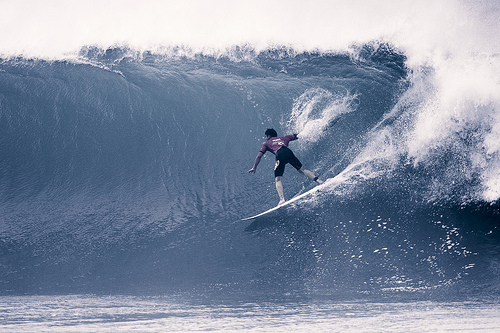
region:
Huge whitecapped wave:
[5, 5, 495, 326]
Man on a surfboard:
[241, 123, 330, 222]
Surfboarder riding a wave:
[2, 35, 497, 327]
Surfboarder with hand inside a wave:
[233, 125, 324, 220]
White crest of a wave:
[1, 18, 499, 82]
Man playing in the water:
[246, 125, 327, 205]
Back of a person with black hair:
[248, 126, 325, 205]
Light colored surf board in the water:
[238, 181, 333, 221]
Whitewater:
[414, 43, 497, 204]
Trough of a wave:
[0, 260, 498, 332]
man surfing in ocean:
[228, 75, 430, 231]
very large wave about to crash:
[16, 23, 430, 297]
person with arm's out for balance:
[229, 110, 377, 231]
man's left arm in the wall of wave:
[277, 112, 328, 151]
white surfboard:
[240, 169, 370, 230]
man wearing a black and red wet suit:
[230, 111, 367, 223]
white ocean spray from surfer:
[399, 29, 478, 157]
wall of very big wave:
[52, 32, 188, 307]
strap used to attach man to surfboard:
[308, 166, 330, 195]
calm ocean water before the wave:
[67, 295, 342, 326]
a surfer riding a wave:
[223, 102, 390, 215]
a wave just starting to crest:
[10, 18, 417, 136]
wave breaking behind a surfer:
[278, 49, 499, 196]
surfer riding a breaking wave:
[214, 93, 385, 222]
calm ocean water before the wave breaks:
[34, 297, 415, 332]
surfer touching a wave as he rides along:
[281, 117, 326, 142]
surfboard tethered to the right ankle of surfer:
[305, 171, 349, 193]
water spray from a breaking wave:
[397, 43, 493, 112]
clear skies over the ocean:
[15, 7, 242, 32]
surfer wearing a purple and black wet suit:
[240, 127, 314, 192]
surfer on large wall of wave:
[5, 40, 495, 316]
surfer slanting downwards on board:
[236, 105, 356, 252]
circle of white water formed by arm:
[282, 70, 357, 147]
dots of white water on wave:
[275, 215, 476, 300]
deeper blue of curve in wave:
[5, 75, 200, 250]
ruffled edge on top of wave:
[5, 26, 395, 67]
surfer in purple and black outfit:
[255, 130, 305, 180]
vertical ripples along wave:
[142, 80, 247, 215]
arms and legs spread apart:
[242, 120, 323, 207]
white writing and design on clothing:
[255, 125, 306, 178]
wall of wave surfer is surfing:
[6, 38, 486, 290]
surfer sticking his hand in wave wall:
[242, 78, 355, 230]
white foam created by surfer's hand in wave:
[279, 83, 351, 144]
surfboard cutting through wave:
[242, 166, 352, 235]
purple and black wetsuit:
[253, 136, 306, 180]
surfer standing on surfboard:
[220, 115, 350, 229]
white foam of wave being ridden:
[20, 21, 497, 198]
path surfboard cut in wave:
[338, 83, 415, 192]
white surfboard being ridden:
[248, 174, 354, 230]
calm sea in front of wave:
[10, 293, 470, 332]